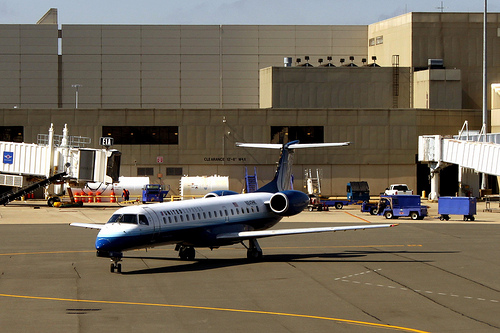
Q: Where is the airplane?
A: Middle of picture.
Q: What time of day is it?
A: Daytime.